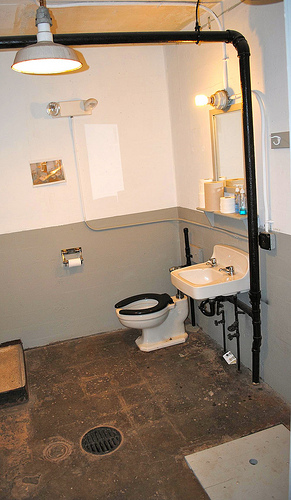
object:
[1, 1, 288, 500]
bathroom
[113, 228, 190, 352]
toilet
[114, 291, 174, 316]
seat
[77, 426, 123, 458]
drain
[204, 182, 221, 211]
paper towels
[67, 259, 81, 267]
toilet paper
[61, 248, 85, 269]
holder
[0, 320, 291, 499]
floor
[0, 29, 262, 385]
piping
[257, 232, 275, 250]
switch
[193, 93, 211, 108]
light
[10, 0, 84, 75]
lamp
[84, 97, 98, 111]
lights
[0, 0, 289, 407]
wall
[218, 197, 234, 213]
toilet paper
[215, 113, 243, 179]
mirror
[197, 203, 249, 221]
shelf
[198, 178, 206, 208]
supplies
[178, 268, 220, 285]
sink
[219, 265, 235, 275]
faucet fixtures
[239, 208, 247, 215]
soap dispenser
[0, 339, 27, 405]
litter box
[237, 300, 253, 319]
pipes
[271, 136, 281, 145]
hook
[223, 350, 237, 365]
paper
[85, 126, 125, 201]
paint mark